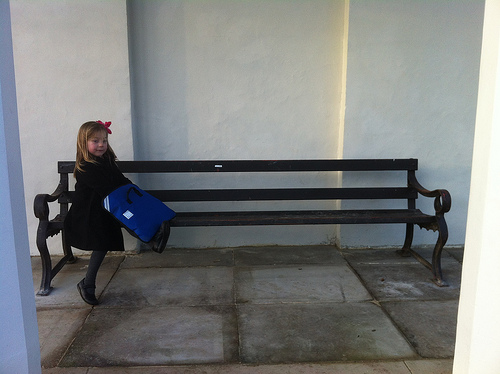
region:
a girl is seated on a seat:
[31, 93, 209, 332]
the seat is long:
[226, 138, 478, 312]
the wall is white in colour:
[183, 22, 260, 146]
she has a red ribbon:
[76, 111, 111, 130]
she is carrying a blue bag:
[81, 173, 174, 264]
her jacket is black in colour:
[66, 172, 133, 239]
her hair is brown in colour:
[76, 120, 88, 162]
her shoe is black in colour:
[77, 264, 111, 321]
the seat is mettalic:
[216, 118, 448, 333]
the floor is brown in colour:
[154, 260, 324, 370]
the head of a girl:
[54, 80, 153, 180]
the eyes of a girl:
[78, 131, 123, 147]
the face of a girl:
[86, 113, 133, 160]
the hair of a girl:
[58, 88, 160, 175]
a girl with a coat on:
[46, 94, 193, 270]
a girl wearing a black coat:
[40, 120, 168, 300]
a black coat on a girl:
[52, 105, 174, 277]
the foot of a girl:
[71, 275, 131, 312]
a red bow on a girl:
[67, 69, 163, 169]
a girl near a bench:
[50, 33, 379, 308]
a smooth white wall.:
[176, 45, 287, 125]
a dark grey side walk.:
[167, 287, 305, 359]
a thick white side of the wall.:
[0, 229, 45, 371]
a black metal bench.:
[180, 153, 460, 288]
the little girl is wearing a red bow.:
[95, 117, 117, 137]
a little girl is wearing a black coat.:
[78, 192, 100, 232]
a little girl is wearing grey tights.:
[84, 252, 102, 279]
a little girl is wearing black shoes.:
[72, 274, 103, 308]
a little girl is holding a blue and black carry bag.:
[98, 179, 180, 243]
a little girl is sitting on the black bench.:
[38, 103, 456, 323]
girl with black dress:
[26, 100, 267, 327]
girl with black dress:
[63, 128, 160, 301]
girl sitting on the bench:
[25, 69, 211, 350]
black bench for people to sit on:
[32, 159, 451, 282]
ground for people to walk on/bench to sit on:
[25, 242, 465, 367]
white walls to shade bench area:
[8, 1, 460, 243]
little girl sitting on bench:
[61, 118, 175, 296]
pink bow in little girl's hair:
[98, 120, 115, 132]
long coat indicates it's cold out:
[63, 158, 121, 255]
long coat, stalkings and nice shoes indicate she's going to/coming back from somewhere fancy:
[62, 118, 124, 307]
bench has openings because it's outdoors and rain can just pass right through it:
[37, 159, 454, 284]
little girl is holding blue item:
[97, 180, 179, 250]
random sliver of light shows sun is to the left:
[317, 2, 352, 194]